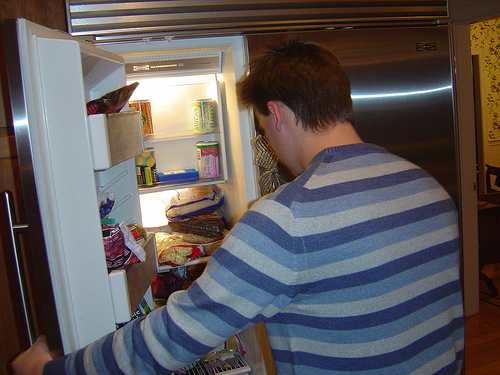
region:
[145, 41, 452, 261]
guy with brown hair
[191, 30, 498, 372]
guy wearing blue striped sweater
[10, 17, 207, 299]
open refrigerator with food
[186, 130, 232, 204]
pink and green on container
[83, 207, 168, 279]
red, white, and blue package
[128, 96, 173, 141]
orange container in refrigerator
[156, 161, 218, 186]
blue item on shelf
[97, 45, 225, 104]
light on in refrigerator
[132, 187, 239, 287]
food on shelf in refrigerator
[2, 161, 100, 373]
metal handle on refrigerator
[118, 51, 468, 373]
Man looking in fridge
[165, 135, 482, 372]
Striped long sleeve sweater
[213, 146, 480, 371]
Dark blue, light blue, and white sweater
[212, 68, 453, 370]
Man turned around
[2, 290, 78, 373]
Man's hand holding fridge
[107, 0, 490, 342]
Stainless steel fridge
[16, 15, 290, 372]
Open freezer door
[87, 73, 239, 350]
Food in freezer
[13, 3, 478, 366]
Man in kitchen looking in freezer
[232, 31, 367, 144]
Man has brown hair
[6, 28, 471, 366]
A man wearing a blue and gray sweater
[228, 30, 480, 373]
A man with brown hair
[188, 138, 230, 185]
A can of frozen juice concentrate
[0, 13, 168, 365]
A refridgerator door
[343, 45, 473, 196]
A silver refridgerator door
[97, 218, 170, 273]
A bag of frozen fruit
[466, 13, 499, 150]
Floral print wallpaper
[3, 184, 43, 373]
A silver refridgerator door handle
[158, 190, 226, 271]
Frozen food in a freezer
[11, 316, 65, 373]
A man's hand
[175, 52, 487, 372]
Boy looking in refridgerater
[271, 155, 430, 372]
Blue striped long sleeve shirt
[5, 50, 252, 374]
Refrigerator with a variety of food.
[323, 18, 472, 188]
Stainless Steel appliance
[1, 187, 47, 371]
Refrigerator Door handle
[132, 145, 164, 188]
Orange juice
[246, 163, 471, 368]
Different shades of blue stripped shirt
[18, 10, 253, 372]
Many selections of food in the refrigerator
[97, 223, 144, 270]
Frozen fruit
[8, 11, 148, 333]
White interior door panal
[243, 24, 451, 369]
this is a man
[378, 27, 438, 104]
this is a fridge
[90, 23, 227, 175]
the fridge is open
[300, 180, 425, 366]
the sweater is blue in color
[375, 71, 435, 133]
the fridge is shiny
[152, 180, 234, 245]
the food are in the fridge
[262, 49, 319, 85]
the hair is short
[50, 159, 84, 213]
the fridge is white in color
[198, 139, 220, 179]
this is a container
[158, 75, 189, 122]
the light is on